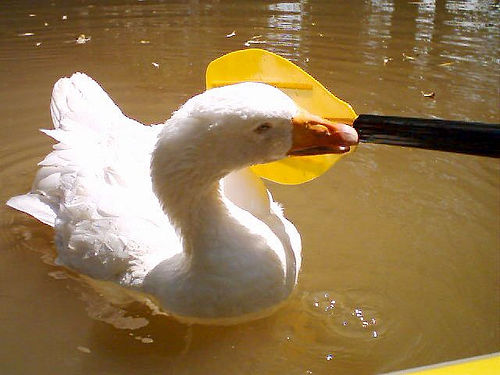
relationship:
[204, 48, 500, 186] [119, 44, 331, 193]
paddle with head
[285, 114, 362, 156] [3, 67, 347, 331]
beak of duck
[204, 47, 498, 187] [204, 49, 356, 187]
paddle made of plastic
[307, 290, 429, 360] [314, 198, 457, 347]
ripple in water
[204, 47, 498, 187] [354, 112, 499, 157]
paddle has pole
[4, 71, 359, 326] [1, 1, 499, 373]
duck in water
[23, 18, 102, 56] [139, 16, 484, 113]
leaves in water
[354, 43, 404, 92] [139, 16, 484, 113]
leaf in water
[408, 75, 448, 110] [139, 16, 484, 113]
leaf in water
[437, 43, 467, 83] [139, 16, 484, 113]
leaf in water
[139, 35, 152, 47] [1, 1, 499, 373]
leaf floating in water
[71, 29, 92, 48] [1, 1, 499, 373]
leaf floating in water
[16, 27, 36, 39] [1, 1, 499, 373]
leaf floating in water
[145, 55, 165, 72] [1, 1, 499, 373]
leaf floating in water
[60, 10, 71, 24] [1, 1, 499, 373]
leaf floating in water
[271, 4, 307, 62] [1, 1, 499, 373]
light reflecting off water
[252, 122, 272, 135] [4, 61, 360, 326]
eye part of swan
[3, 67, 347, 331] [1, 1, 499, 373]
duck in water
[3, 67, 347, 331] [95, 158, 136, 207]
duck has feathers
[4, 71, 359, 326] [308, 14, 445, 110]
duck swimming water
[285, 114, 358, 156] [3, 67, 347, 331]
beak on duck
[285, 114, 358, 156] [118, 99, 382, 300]
beak on duck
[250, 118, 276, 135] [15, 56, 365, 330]
eye on duck